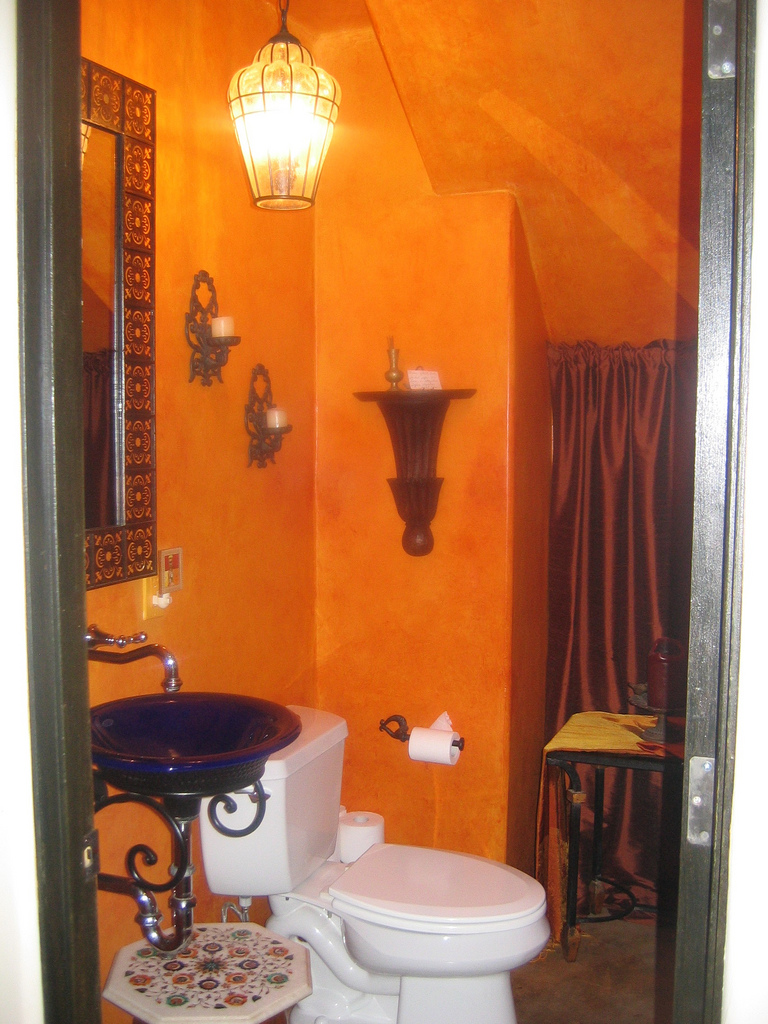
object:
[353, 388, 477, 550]
wooden shelf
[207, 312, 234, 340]
candle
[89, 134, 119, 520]
mirror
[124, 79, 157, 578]
patterned frame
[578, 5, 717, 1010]
door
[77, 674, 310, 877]
sink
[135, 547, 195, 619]
charger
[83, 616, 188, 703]
faucet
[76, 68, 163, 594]
mirror frame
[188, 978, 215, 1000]
octagon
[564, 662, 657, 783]
cloth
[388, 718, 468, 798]
toilet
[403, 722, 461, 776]
roll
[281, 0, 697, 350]
ceiling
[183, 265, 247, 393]
candle holder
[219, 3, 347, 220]
light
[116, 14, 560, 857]
wall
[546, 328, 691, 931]
curtain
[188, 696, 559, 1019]
toilet